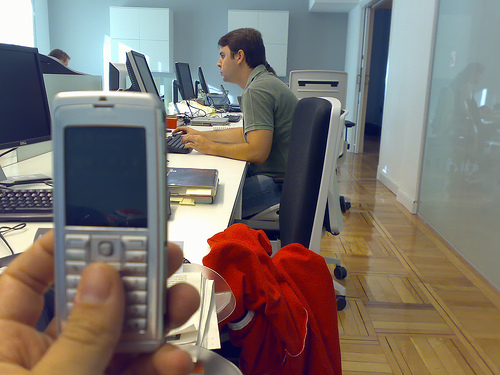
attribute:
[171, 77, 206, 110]
flatscreen monitors —  flatscreen, in row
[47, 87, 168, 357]
cell phone — held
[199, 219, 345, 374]
jacket — red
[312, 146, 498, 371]
floor — parkay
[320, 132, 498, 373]
floor — tan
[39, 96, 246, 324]
cell phone —  old model 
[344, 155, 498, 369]
floor —  Wooden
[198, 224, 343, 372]
shirt — red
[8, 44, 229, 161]
monitors — computer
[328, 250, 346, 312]
wheels — black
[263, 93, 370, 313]
desk chair —  desk's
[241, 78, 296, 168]
polo shirt — green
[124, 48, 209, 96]
three monitors —  computer's 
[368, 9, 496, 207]
glass divider — opaque